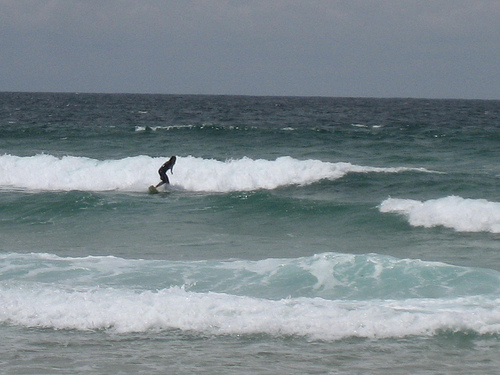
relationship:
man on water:
[154, 156, 187, 182] [267, 109, 384, 232]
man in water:
[154, 156, 187, 182] [267, 109, 384, 232]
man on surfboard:
[154, 156, 187, 182] [149, 185, 156, 196]